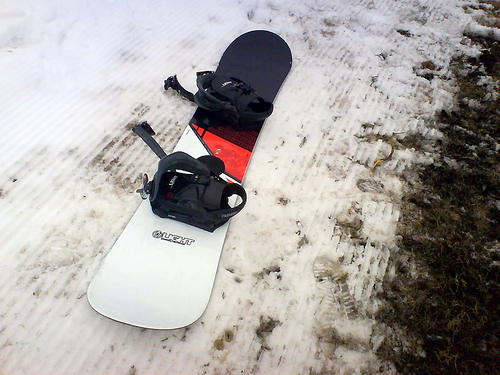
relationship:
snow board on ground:
[86, 29, 294, 331] [318, 21, 472, 365]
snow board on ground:
[86, 29, 294, 331] [3, 0, 498, 370]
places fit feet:
[132, 71, 272, 231] [141, 61, 280, 221]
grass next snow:
[0, 0, 498, 374] [2, 0, 497, 375]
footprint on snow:
[312, 252, 363, 328] [2, 0, 497, 375]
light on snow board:
[159, 230, 196, 247] [86, 29, 294, 331]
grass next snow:
[380, 30, 492, 374] [5, 1, 421, 373]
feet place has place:
[149, 67, 275, 231] [145, 72, 278, 213]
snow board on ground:
[87, 14, 302, 335] [3, 0, 498, 370]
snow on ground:
[0, 0, 499, 374] [3, 0, 498, 370]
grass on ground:
[0, 0, 498, 374] [340, 2, 498, 373]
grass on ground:
[0, 0, 498, 374] [279, 67, 384, 217]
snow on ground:
[70, 58, 179, 115] [3, 0, 498, 370]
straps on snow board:
[133, 121, 169, 160] [86, 29, 294, 331]